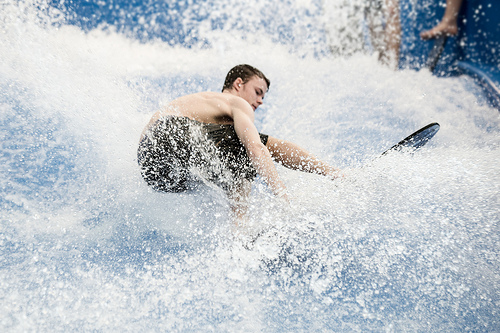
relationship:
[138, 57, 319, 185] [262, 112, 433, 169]
boy on surfboard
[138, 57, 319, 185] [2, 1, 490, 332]
boy in water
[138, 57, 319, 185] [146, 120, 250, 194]
boy wearing shorts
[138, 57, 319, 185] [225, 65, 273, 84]
boy with hair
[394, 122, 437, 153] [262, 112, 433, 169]
tip of surfboard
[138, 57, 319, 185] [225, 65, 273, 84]
boy has hair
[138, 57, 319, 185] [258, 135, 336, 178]
boy has leg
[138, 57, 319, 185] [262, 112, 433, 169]
boy holding onto surfboard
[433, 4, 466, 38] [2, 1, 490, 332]
leg over water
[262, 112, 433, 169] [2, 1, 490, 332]
surfboard in water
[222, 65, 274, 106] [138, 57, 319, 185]
head of boy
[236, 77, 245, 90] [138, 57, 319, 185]
ear of boy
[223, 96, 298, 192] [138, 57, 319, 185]
arm of boy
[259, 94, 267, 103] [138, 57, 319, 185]
nose of boy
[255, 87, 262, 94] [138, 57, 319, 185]
eye of boy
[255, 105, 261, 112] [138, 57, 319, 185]
mouth of boy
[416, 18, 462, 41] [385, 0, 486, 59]
foot of person